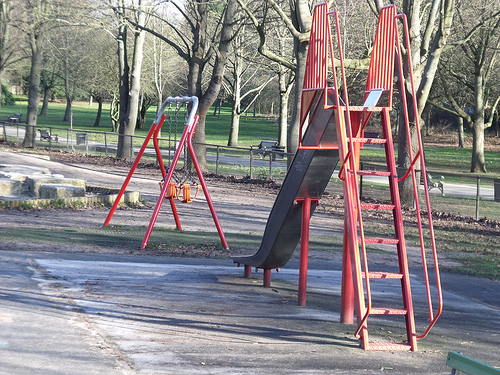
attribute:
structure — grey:
[0, 170, 140, 210]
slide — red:
[304, 9, 448, 374]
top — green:
[450, 356, 499, 373]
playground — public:
[1, 124, 498, 372]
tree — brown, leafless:
[427, 0, 499, 172]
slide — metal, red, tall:
[233, 3, 445, 353]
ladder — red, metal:
[335, 105, 443, 353]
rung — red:
[347, 137, 387, 145]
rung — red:
[355, 170, 391, 177]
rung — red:
[360, 203, 395, 211]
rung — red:
[362, 270, 404, 279]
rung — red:
[366, 307, 408, 315]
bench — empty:
[38, 128, 57, 142]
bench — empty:
[250, 141, 279, 159]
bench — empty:
[421, 172, 445, 198]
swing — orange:
[175, 184, 199, 204]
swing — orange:
[159, 182, 176, 201]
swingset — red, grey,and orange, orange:
[103, 97, 230, 252]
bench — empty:
[8, 113, 23, 123]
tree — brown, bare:
[6, 1, 79, 150]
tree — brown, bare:
[103, 1, 165, 162]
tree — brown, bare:
[159, 0, 258, 173]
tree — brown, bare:
[238, 1, 371, 175]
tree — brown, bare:
[266, 19, 294, 153]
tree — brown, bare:
[221, 1, 280, 150]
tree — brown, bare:
[363, 0, 462, 209]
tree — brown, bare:
[439, 0, 499, 173]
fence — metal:
[0, 120, 498, 229]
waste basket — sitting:
[75, 133, 89, 145]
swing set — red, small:
[100, 94, 230, 252]